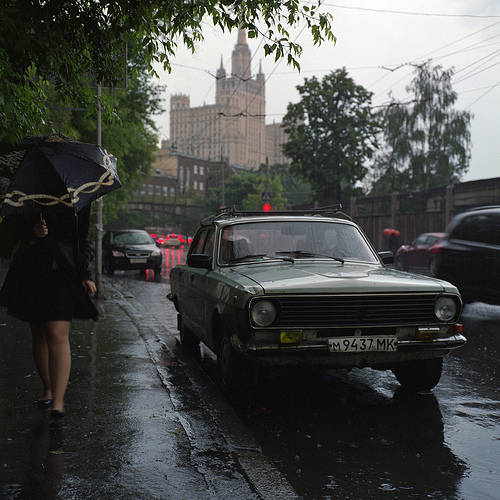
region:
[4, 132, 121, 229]
black and gold umbrella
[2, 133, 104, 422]
woman wearing a black dress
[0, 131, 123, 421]
woman carrying an umbrella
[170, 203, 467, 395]
old car with white license plate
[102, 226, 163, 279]
shiny black car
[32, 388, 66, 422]
pair of black flat shoes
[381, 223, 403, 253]
person with a red umbrella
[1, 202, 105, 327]
Woman is wearing a black dress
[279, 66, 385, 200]
Green leaves on a tree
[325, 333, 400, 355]
A white rectangular license plate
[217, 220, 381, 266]
Front window of a car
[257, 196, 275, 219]
Traffic light lit up red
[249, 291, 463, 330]
Two round headlights on a car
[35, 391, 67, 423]
A pair of black shoes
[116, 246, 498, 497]
The street is wet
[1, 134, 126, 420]
A lady is holding an umbrella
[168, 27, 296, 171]
A tall brown building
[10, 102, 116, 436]
Woman holding an umbrella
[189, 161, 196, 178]
Small window on a building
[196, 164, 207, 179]
Small window on a building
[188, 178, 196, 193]
Small window on a building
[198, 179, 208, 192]
Small window on a building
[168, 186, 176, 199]
Small window on a building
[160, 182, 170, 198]
Small window on a building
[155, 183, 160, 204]
Small window on a building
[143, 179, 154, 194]
Small window on a building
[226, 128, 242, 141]
Small window on a building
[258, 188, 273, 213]
red illuminated traffic control light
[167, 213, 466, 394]
a small green car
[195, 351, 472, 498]
shadow of the car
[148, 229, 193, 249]
tail lights of vehicles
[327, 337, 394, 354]
white car tag with black writing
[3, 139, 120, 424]
woman walking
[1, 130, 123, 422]
woman wearing a black outfit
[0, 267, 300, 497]
sidewalk is wet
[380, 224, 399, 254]
a person carrying a red umbrella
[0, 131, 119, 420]
Lady holding an umbrella and walking.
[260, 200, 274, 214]
Red stop light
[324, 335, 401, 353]
License plate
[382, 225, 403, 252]
Person holding red umbrella.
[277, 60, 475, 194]
Trees in the background.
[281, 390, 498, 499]
Puddle on the ground.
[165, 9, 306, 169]
Large building in the background.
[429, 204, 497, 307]
Car moving through photograph.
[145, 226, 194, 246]
Brake lights in the background.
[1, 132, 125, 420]
A woman holding an umbrella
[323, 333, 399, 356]
A white license plate